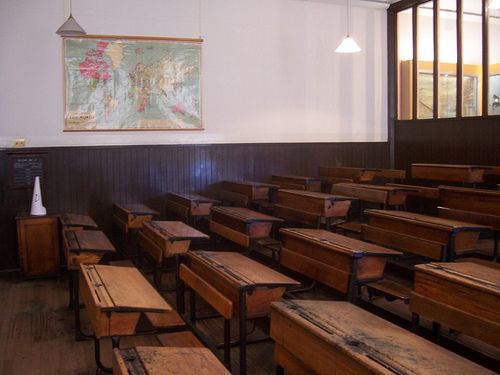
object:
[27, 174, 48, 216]
cone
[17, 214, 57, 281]
table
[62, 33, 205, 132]
map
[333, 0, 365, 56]
light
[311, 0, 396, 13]
ceiling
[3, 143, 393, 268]
paneling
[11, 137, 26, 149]
switch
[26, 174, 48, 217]
cap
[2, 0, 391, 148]
wall